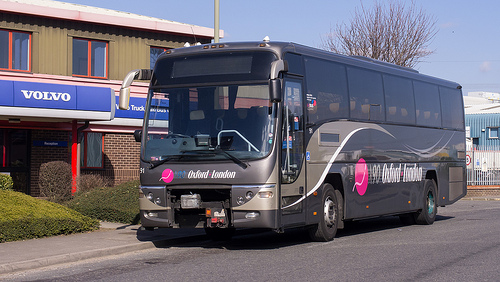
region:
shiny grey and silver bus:
[117, 42, 472, 238]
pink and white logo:
[347, 155, 371, 197]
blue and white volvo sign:
[1, 78, 111, 123]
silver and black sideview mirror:
[267, 55, 287, 102]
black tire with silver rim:
[315, 179, 340, 241]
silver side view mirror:
[115, 64, 148, 110]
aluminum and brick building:
[1, 1, 226, 208]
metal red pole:
[67, 118, 79, 196]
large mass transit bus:
[114, 36, 469, 241]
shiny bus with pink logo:
[117, 35, 467, 237]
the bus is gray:
[131, 37, 477, 249]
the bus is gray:
[107, 13, 474, 257]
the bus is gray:
[131, 35, 478, 244]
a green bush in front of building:
[45, 158, 78, 203]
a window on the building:
[72, 29, 118, 86]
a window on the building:
[4, 29, 36, 93]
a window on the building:
[136, 42, 162, 86]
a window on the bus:
[301, 55, 363, 130]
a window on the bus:
[341, 64, 392, 129]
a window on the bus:
[384, 71, 419, 132]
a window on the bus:
[411, 83, 443, 124]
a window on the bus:
[151, 84, 247, 156]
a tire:
[321, 183, 345, 248]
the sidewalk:
[25, 238, 46, 258]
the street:
[306, 257, 343, 280]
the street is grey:
[358, 233, 407, 272]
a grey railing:
[216, 128, 241, 140]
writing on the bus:
[373, 162, 426, 193]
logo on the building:
[13, 85, 71, 105]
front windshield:
[151, 88, 271, 152]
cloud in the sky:
[476, 58, 493, 74]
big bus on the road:
[110, 30, 480, 245]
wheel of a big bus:
[313, 178, 349, 245]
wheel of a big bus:
[412, 172, 444, 223]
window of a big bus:
[380, 71, 424, 126]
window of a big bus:
[142, 80, 273, 156]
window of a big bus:
[280, 71, 301, 149]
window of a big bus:
[301, 57, 347, 123]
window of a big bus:
[345, 58, 386, 133]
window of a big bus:
[380, 67, 415, 127]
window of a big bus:
[440, 82, 464, 129]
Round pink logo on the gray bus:
[351, 152, 369, 195]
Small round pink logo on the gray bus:
[160, 167, 173, 181]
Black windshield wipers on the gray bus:
[148, 147, 247, 172]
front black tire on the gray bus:
[314, 176, 340, 240]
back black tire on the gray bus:
[420, 173, 439, 223]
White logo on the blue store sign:
[20, 87, 70, 104]